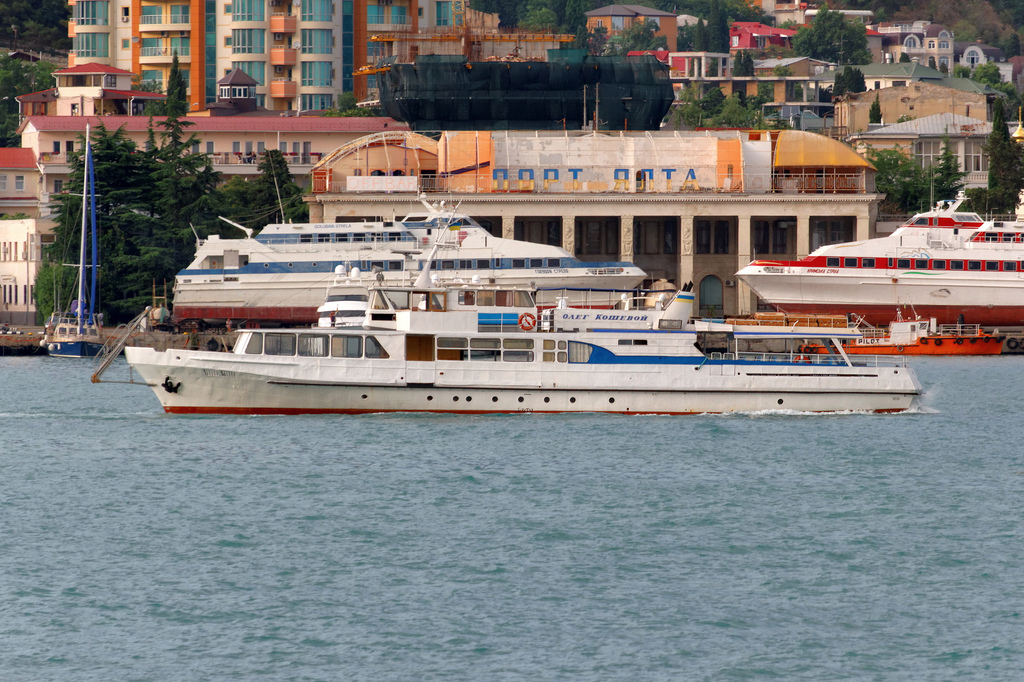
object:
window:
[291, 50, 342, 94]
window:
[288, 54, 336, 121]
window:
[46, 66, 74, 92]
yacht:
[138, 177, 669, 334]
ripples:
[839, 552, 922, 593]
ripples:
[177, 449, 249, 493]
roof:
[0, 91, 408, 150]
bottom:
[137, 389, 931, 437]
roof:
[724, 124, 879, 181]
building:
[0, 0, 1024, 343]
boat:
[799, 287, 1023, 371]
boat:
[9, 122, 142, 386]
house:
[1, 80, 422, 190]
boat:
[703, 142, 1023, 325]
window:
[296, 26, 335, 57]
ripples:
[503, 525, 578, 571]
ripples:
[183, 517, 239, 560]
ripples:
[185, 588, 270, 652]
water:
[0, 337, 1024, 682]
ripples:
[109, 428, 192, 472]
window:
[233, 308, 269, 362]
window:
[294, 329, 333, 361]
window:
[329, 329, 348, 360]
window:
[357, 331, 397, 372]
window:
[393, 321, 440, 365]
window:
[429, 326, 474, 366]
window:
[467, 327, 504, 371]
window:
[499, 335, 538, 352]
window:
[554, 335, 575, 351]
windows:
[582, 209, 606, 260]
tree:
[17, 92, 254, 376]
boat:
[68, 298, 969, 484]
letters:
[561, 305, 571, 324]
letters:
[487, 162, 515, 199]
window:
[392, 320, 446, 377]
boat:
[87, 256, 900, 566]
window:
[565, 329, 602, 376]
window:
[355, 314, 400, 367]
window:
[499, 328, 544, 371]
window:
[359, 275, 419, 320]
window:
[433, 331, 478, 354]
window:
[470, 282, 501, 307]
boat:
[191, 183, 882, 355]